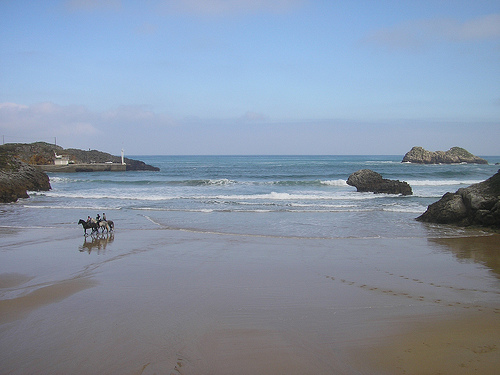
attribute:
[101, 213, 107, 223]
person — horseback ridding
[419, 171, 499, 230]
rock — here, big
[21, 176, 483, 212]
waves — foamy, heavy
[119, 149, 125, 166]
pole — tall, white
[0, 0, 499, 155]
sky — clear, blue, cloudy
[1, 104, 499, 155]
clouds — white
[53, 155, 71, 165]
beach house — white, here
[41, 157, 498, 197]
ocean — blue, big, here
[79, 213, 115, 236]
horses — walking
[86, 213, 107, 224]
people — here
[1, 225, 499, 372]
beach — wet, here, brown, sandy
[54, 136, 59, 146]
tower — here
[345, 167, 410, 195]
boulder — grey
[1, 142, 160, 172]
mountain — here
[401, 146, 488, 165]
rock island — here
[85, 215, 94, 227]
person — horseback ridding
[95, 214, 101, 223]
person — horseback ridding